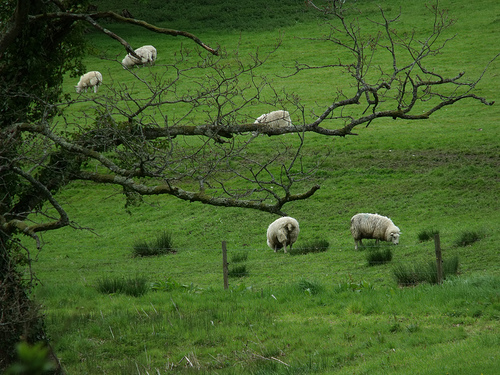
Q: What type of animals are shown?
A: Sheep.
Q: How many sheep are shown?
A: 5.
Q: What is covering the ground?
A: Grass.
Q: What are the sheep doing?
A: Eating.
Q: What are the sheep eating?
A: Grass.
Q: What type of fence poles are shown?
A: Wooden.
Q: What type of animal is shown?
A: Sheep.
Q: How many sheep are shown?
A: Five.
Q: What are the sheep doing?
A: Eating.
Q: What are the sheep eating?
A: Grass.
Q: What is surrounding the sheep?
A: Fence.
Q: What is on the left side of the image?
A: Tree.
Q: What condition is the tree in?
A: Bare.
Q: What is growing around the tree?
A: Vine.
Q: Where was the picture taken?
A: In a pasture.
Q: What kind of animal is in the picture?
A: Sheep.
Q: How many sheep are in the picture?
A: 6.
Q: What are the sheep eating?
A: Grass.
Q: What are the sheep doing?
A: Grazing.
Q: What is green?
A: The grass.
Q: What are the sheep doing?
A: Grazing.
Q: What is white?
A: Sheep.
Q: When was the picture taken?
A: Daytime.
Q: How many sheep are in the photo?
A: Five.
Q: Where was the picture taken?
A: On a grassy field.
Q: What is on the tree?
A: Leaves.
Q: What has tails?
A: The sheep.